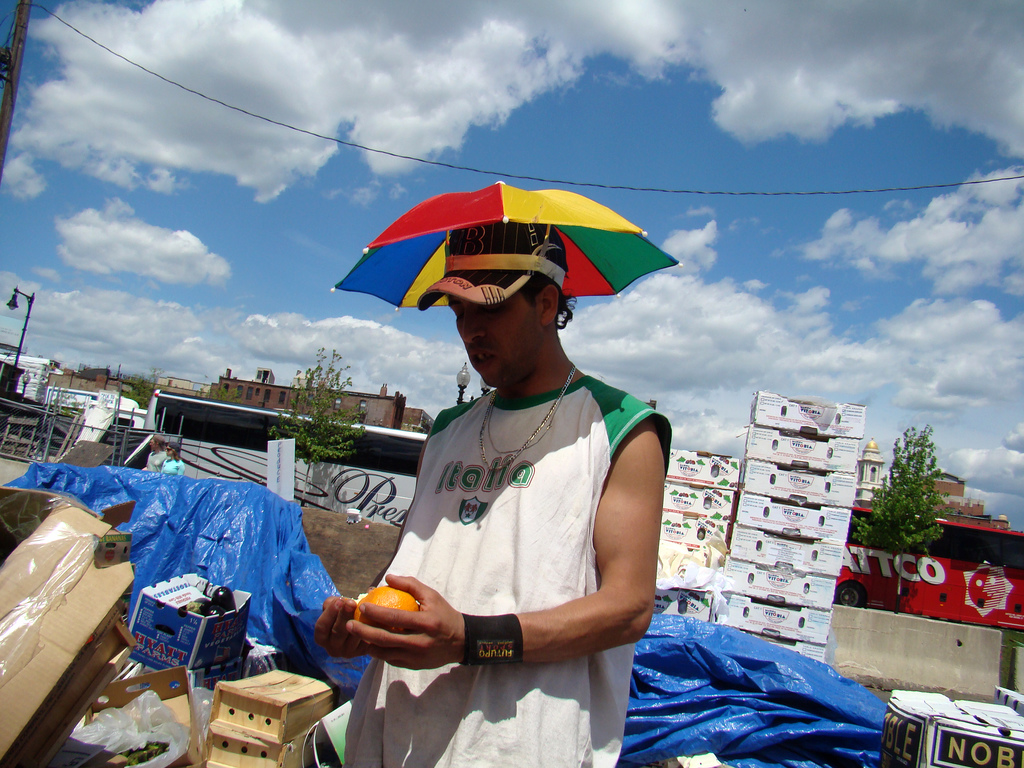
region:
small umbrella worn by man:
[326, 158, 677, 296]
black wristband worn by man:
[461, 604, 528, 674]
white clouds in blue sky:
[891, 323, 931, 368]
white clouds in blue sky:
[669, 262, 737, 327]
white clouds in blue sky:
[683, 328, 750, 376]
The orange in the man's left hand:
[348, 580, 418, 628]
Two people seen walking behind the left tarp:
[140, 427, 186, 481]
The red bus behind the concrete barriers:
[830, 499, 1023, 633]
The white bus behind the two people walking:
[140, 377, 436, 539]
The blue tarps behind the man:
[14, 456, 891, 764]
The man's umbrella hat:
[324, 169, 695, 326]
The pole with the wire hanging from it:
[0, 4, 40, 201]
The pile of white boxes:
[643, 383, 871, 677]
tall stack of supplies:
[715, 390, 870, 663]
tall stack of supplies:
[649, 445, 739, 623]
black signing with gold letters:
[873, 687, 1019, 765]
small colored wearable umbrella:
[332, 179, 678, 309]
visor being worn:
[414, 239, 569, 316]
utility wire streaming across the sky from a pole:
[1, 1, 1017, 199]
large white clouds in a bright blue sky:
[3, 3, 1019, 522]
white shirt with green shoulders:
[342, 374, 674, 766]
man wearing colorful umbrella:
[297, 166, 671, 309]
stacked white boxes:
[702, 377, 851, 602]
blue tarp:
[661, 611, 871, 761]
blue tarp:
[101, 454, 302, 597]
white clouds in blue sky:
[84, 59, 155, 142]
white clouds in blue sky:
[49, 178, 142, 240]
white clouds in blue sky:
[154, 118, 231, 183]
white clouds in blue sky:
[315, 103, 399, 170]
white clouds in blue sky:
[536, 24, 632, 85]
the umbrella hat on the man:
[328, 181, 684, 302]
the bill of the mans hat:
[416, 266, 533, 311]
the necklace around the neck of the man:
[474, 363, 577, 477]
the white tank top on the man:
[343, 376, 673, 766]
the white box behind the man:
[879, 692, 1020, 766]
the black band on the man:
[461, 611, 523, 672]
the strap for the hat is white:
[442, 253, 569, 286]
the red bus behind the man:
[833, 505, 1023, 629]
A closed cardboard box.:
[743, 457, 852, 508]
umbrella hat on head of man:
[333, 171, 660, 293]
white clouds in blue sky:
[29, 16, 128, 77]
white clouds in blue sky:
[231, 45, 280, 100]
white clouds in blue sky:
[105, 201, 163, 259]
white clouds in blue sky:
[462, 48, 526, 100]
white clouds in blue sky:
[541, 40, 669, 171]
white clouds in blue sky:
[725, 57, 824, 162]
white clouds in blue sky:
[810, 168, 921, 261]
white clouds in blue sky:
[655, 282, 707, 352]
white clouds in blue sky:
[825, 201, 930, 288]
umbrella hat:
[344, 151, 658, 308]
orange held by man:
[352, 546, 430, 649]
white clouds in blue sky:
[88, 81, 181, 164]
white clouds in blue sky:
[703, 42, 860, 183]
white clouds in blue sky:
[808, 230, 913, 291]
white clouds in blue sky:
[406, 61, 533, 126]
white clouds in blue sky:
[71, 186, 167, 266]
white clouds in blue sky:
[207, 305, 278, 363]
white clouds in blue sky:
[675, 305, 793, 372]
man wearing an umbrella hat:
[329, 178, 681, 395]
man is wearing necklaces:
[478, 365, 588, 473]